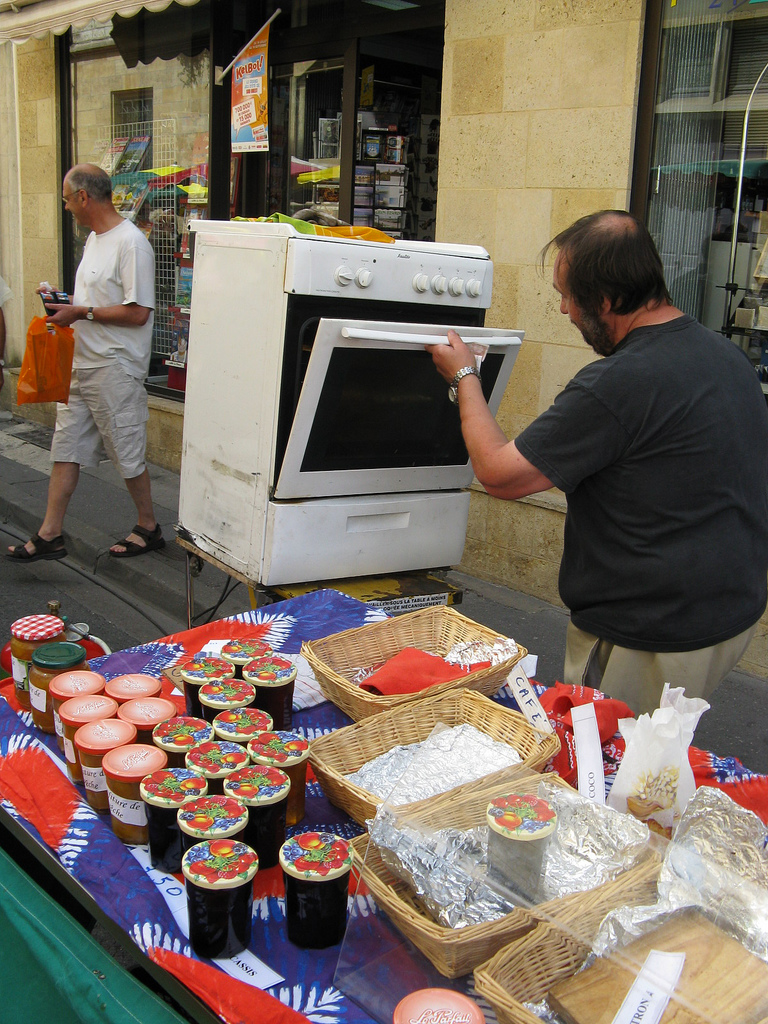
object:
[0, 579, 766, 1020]
table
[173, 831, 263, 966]
jar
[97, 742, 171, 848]
jar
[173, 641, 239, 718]
jar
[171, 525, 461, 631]
cart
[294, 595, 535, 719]
basket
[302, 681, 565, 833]
basket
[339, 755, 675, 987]
basket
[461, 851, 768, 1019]
basket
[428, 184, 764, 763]
man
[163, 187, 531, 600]
oven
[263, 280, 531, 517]
door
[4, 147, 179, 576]
man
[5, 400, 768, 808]
sidewalk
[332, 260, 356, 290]
knob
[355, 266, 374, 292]
knob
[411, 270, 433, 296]
knob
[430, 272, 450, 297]
knob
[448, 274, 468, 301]
knob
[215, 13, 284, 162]
flag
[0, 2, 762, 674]
building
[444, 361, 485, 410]
watch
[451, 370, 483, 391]
wrist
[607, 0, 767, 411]
window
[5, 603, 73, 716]
jar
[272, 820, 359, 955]
jar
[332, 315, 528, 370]
handle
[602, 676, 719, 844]
bag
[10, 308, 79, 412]
bag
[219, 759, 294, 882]
jar